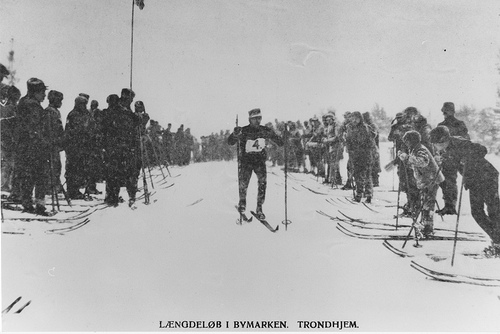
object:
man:
[228, 108, 285, 206]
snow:
[186, 233, 264, 267]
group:
[0, 64, 161, 217]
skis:
[336, 223, 487, 242]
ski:
[250, 210, 280, 232]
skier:
[219, 75, 308, 275]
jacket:
[228, 124, 285, 164]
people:
[387, 102, 499, 259]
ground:
[0, 170, 500, 334]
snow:
[404, 283, 458, 313]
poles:
[235, 114, 290, 235]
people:
[265, 111, 382, 203]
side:
[261, 0, 500, 334]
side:
[3, 0, 220, 334]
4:
[252, 140, 260, 150]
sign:
[245, 138, 266, 153]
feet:
[238, 201, 247, 212]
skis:
[234, 204, 279, 234]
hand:
[281, 129, 293, 139]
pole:
[285, 121, 289, 231]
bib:
[239, 132, 269, 164]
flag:
[133, 1, 148, 11]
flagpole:
[128, 2, 136, 90]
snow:
[180, 274, 285, 317]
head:
[248, 108, 262, 127]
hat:
[248, 108, 262, 120]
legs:
[238, 165, 267, 208]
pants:
[238, 159, 267, 206]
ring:
[281, 219, 292, 225]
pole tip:
[285, 225, 288, 231]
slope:
[3, 161, 496, 331]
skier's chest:
[244, 130, 267, 152]